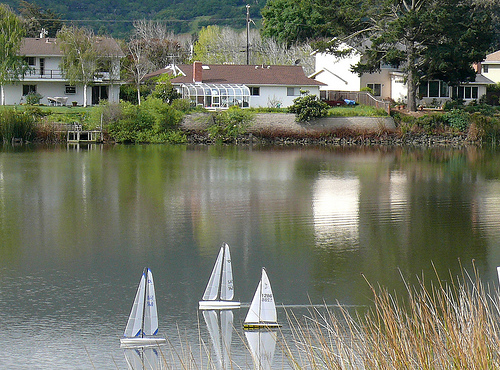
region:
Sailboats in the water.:
[73, 251, 296, 350]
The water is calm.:
[175, 142, 424, 241]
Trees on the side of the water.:
[108, 100, 183, 144]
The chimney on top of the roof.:
[186, 58, 226, 85]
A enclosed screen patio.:
[168, 82, 251, 119]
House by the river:
[188, 56, 324, 113]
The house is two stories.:
[8, 43, 135, 124]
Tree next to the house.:
[353, 6, 456, 114]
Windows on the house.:
[14, 80, 99, 96]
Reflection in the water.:
[238, 153, 426, 236]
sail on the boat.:
[205, 253, 220, 295]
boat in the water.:
[253, 260, 278, 324]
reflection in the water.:
[323, 174, 358, 248]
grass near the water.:
[391, 299, 477, 354]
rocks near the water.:
[378, 136, 435, 146]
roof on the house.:
[246, 71, 269, 81]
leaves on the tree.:
[427, 12, 450, 27]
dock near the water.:
[59, 129, 101, 141]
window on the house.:
[287, 88, 302, 95]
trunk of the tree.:
[407, 57, 418, 105]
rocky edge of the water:
[190, 127, 482, 149]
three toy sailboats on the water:
[117, 241, 286, 355]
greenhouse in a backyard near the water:
[172, 79, 250, 111]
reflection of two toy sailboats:
[194, 310, 281, 367]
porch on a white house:
[391, 63, 496, 110]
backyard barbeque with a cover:
[40, 90, 69, 108]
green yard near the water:
[0, 99, 102, 127]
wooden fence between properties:
[320, 81, 394, 118]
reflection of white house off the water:
[300, 162, 417, 257]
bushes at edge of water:
[106, 96, 188, 146]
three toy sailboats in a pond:
[109, 238, 291, 349]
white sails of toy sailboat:
[122, 265, 167, 339]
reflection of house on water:
[309, 152, 419, 252]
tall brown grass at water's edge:
[315, 271, 499, 364]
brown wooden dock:
[23, 118, 106, 157]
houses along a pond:
[22, 33, 492, 111]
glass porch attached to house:
[177, 78, 252, 112]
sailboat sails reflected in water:
[206, 328, 286, 363]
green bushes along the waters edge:
[116, 103, 186, 144]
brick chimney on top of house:
[190, 57, 213, 82]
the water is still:
[194, 137, 456, 291]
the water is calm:
[7, 134, 367, 248]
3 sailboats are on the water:
[77, 222, 294, 355]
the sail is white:
[233, 261, 290, 348]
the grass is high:
[290, 277, 498, 365]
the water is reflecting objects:
[179, 132, 473, 243]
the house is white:
[0, 22, 140, 112]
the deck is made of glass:
[152, 66, 269, 130]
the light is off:
[240, 2, 261, 64]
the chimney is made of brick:
[174, 52, 219, 88]